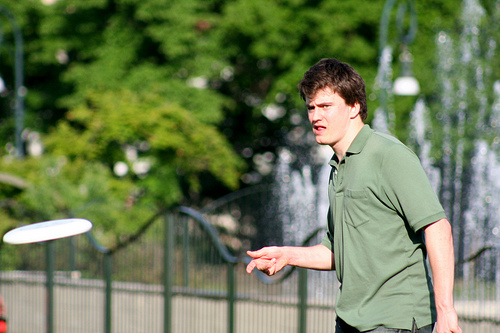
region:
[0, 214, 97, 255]
white frisbee in air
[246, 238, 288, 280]
the man's right hand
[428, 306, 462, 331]
the man's left hand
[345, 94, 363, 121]
the man's left ear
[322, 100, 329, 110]
left eye on the man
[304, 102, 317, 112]
the man's right eye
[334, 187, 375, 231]
pocket on the man's shirt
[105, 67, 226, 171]
leaves on the tree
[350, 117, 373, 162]
collar on the man's shirt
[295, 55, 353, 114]
boy has brown hair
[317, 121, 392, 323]
boy has green shirt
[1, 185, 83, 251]
white frisbee in air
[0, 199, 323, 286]
boy is throwing frisbee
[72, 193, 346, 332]
green fence behind boy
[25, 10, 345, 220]
green and leafy trees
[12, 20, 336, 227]
trees are behind fence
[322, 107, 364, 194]
green collar on shirt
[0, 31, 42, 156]
green pole in trees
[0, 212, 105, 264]
the frisbbe is in the air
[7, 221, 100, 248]
the frisbee is white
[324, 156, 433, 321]
the shirt is green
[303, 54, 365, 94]
the hair is brown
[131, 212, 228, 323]
the fence is made of metal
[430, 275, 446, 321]
veins are on the hand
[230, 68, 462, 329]
the man is outdoors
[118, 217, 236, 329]
the fence is metal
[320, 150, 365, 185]
the shirt is unbottoned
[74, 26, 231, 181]
the background is blurred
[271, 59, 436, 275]
man is dressed in a green t shirt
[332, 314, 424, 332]
the pants are black in color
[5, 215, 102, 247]
the frisbeel is white in color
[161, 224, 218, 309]
the fence is made of ,metal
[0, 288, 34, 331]
an orange cloth at the edge of the picture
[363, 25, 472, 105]
plants are green in color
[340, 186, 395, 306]
the t shirt is green in color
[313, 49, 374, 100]
the hair is black in color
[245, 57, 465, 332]
man playing game of frisbee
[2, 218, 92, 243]
white Frisbee hovering in air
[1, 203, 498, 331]
green wrought iron fence behind man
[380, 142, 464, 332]
man's left arm at his side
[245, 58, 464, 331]
man with dark brown hair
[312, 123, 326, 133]
open mouth on man's face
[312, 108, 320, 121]
nose on man's face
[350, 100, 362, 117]
ear on left side of man's head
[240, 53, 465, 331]
man in green shirt making a funny face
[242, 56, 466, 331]
man with dark hair making a funny face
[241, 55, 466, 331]
man with green shirt has just thrown a frisbee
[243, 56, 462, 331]
man with dark hair has just thrown a frisbee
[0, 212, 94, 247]
frisbee the man in green shirt threw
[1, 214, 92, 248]
frisbee the man with dark hair just threw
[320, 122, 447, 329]
green shirt of the man throwing the frisbee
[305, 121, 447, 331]
green shirt of the man with dark hair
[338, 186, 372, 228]
pocket of green shirt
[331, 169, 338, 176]
button of green shirt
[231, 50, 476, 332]
man wearing green shirt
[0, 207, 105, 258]
white disc in the air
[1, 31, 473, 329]
man tossing white disc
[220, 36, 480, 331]
man standing with mouth open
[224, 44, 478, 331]
dark haired man in green shirt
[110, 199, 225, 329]
green metal fencing and posts